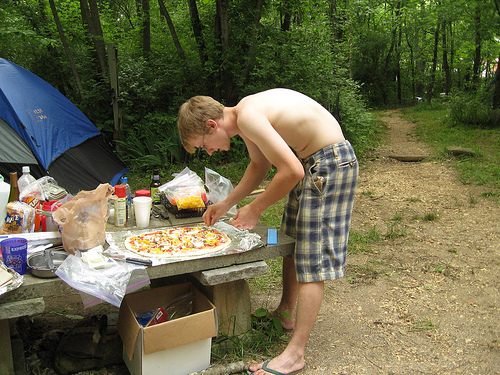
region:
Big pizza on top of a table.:
[153, 247, 160, 259]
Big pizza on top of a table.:
[219, 239, 231, 246]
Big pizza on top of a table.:
[182, 217, 194, 239]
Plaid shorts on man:
[285, 145, 356, 282]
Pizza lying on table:
[126, 224, 230, 257]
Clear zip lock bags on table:
[59, 253, 150, 308]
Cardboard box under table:
[121, 292, 223, 373]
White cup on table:
[132, 193, 152, 228]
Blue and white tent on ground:
[4, 58, 103, 164]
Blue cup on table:
[4, 238, 28, 274]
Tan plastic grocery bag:
[48, 187, 110, 247]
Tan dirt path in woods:
[356, 102, 498, 366]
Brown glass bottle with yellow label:
[150, 167, 160, 207]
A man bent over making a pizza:
[121, 79, 361, 373]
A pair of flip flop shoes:
[249, 310, 313, 372]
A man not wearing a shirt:
[169, 70, 366, 373]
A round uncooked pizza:
[117, 215, 234, 257]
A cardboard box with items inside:
[119, 285, 219, 373]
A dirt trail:
[338, 87, 498, 367]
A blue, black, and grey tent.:
[1, 57, 132, 220]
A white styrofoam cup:
[133, 196, 152, 230]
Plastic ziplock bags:
[55, 248, 154, 314]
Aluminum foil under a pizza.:
[104, 218, 261, 267]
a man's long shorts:
[281, 142, 368, 284]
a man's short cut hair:
[175, 93, 233, 156]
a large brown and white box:
[115, 280, 230, 373]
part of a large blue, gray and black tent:
[1, 59, 127, 201]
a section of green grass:
[410, 100, 497, 187]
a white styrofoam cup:
[133, 196, 155, 228]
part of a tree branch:
[181, 1, 217, 61]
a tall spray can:
[114, 183, 135, 227]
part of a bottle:
[16, 165, 32, 189]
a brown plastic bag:
[56, 185, 116, 251]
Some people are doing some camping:
[5, 27, 493, 364]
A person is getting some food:
[6, 33, 477, 368]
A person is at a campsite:
[5, 25, 495, 360]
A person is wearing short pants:
[7, 35, 497, 370]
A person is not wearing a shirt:
[5, 57, 436, 372]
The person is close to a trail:
[1, 40, 481, 370]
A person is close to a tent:
[5, 50, 465, 350]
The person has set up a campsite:
[0, 61, 485, 357]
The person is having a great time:
[10, 55, 431, 360]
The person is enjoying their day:
[10, 33, 427, 348]